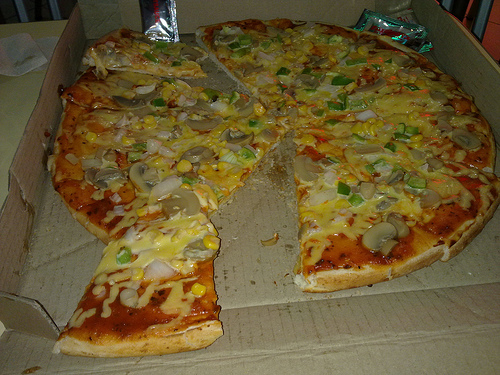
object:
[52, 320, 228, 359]
crust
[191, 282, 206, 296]
corn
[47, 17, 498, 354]
pizza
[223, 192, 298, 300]
cardboard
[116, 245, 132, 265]
bell pepper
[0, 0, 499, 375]
box